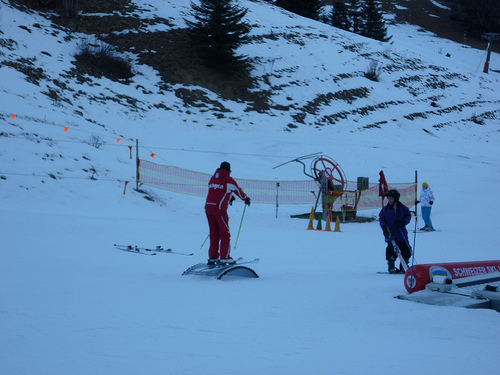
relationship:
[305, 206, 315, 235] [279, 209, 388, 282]
cone on snow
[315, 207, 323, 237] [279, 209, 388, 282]
cone on snow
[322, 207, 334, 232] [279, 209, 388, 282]
cone on snow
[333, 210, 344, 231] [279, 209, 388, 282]
cone on snow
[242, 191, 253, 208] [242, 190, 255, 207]
glove on hand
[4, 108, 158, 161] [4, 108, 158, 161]
flag on flag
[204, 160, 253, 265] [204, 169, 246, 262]
man in snowsuit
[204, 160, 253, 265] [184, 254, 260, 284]
man on surface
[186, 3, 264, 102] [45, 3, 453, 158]
tree in snow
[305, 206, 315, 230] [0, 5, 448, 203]
cone on hillside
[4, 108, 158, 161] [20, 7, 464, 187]
flag on mountainside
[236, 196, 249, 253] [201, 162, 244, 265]
pole of man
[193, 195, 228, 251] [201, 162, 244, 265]
pole of man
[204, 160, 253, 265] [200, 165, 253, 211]
man wearing jacket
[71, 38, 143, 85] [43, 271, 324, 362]
patches in snow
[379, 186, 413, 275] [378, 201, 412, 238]
person wearing coat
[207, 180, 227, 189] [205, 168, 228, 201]
lettering on background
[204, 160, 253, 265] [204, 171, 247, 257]
man in suit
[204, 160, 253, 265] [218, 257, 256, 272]
man balancing skis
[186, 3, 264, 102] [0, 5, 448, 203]
tree on hillside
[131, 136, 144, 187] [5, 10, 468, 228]
pole on hillside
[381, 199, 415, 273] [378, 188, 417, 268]
suit in skier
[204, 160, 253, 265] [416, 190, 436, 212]
man in coat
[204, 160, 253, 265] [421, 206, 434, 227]
man in pants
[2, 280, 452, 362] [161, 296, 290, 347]
ground covered snow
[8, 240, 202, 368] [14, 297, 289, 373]
snow covering ground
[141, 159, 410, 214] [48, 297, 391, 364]
barrier in snow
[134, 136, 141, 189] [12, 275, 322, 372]
pole in snow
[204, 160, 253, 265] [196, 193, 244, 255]
man wearing skies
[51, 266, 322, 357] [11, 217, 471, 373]
snow covering ground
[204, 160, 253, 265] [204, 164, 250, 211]
man wearing jacket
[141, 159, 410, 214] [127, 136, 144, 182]
barrier on poles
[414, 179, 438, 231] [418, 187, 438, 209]
person wearing jacket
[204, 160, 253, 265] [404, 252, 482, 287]
man standing object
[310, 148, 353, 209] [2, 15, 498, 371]
fan in snow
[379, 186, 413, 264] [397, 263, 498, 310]
person pulling object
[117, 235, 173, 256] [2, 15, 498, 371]
skis in snow